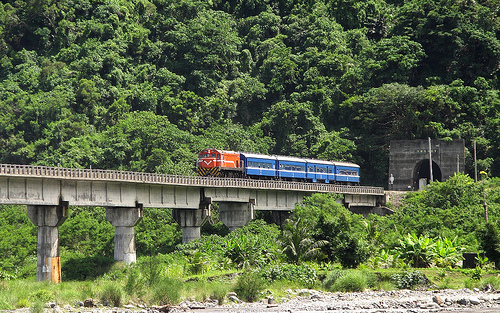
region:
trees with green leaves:
[13, 5, 191, 158]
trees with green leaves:
[144, 20, 350, 138]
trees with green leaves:
[322, 7, 494, 111]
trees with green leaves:
[403, 176, 491, 271]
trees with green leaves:
[290, 193, 387, 279]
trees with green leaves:
[170, 245, 300, 284]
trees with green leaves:
[71, 215, 108, 280]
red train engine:
[197, 139, 242, 176]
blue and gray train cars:
[247, 140, 367, 184]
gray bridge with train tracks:
[21, 150, 190, 231]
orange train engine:
[196, 143, 243, 174]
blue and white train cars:
[246, 149, 306, 181]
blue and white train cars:
[301, 150, 367, 190]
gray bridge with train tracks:
[192, 173, 295, 210]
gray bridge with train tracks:
[23, 200, 70, 280]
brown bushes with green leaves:
[417, 184, 494, 282]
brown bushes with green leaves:
[140, 223, 275, 300]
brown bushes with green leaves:
[19, 12, 189, 153]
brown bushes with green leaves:
[201, 17, 473, 117]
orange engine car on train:
[191, 144, 243, 183]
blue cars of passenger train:
[242, 145, 367, 190]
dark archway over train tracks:
[405, 155, 448, 195]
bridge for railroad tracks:
[10, 160, 185, 285]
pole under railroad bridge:
[94, 193, 146, 270]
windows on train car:
[247, 155, 292, 176]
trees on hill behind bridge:
[172, 68, 339, 138]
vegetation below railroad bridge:
[189, 242, 330, 291]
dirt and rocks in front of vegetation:
[358, 284, 476, 309]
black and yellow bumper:
[194, 165, 223, 178]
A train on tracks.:
[196, 146, 362, 184]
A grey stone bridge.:
[1, 161, 386, 283]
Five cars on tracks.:
[196, 145, 361, 185]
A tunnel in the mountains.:
[386, 139, 465, 191]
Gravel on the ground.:
[1, 287, 498, 310]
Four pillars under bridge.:
[26, 197, 255, 283]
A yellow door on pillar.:
[49, 255, 60, 283]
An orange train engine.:
[196, 146, 242, 176]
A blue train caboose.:
[328, 160, 360, 185]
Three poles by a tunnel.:
[426, 135, 478, 183]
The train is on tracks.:
[170, 137, 380, 197]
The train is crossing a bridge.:
[0, 130, 473, 282]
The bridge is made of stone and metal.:
[0, 125, 476, 278]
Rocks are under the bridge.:
[28, 282, 495, 311]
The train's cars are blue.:
[240, 148, 378, 182]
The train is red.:
[193, 147, 222, 172]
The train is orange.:
[212, 147, 243, 176]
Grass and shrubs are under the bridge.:
[106, 172, 496, 304]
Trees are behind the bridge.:
[1, 1, 487, 141]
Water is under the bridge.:
[381, 282, 498, 312]